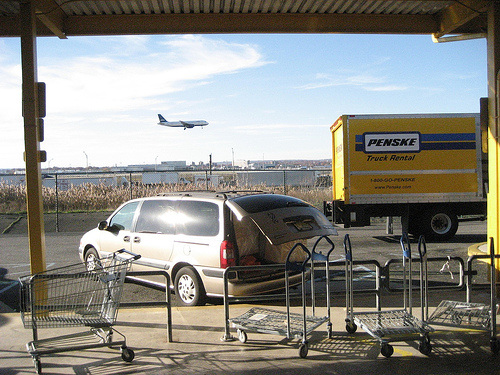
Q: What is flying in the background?
A: Plane.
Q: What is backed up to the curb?
A: Van.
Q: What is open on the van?
A: Trunk.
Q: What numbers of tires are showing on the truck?
A: 2.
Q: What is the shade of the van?
A: Gold.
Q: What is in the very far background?
A: Buildings.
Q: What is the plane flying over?
A: Water.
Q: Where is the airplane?
A: In the air.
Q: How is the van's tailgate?
A: Open.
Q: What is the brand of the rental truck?
A: Penske.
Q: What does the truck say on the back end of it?
A: Penske Truck Rental.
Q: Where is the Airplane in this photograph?
A: In the Air.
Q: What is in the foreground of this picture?
A: Shopping carts.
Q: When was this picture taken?
A: During the day.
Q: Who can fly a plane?
A: A licensed pilot.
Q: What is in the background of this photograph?
A: The Sky.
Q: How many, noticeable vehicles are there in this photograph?
A: Three Vehicles.